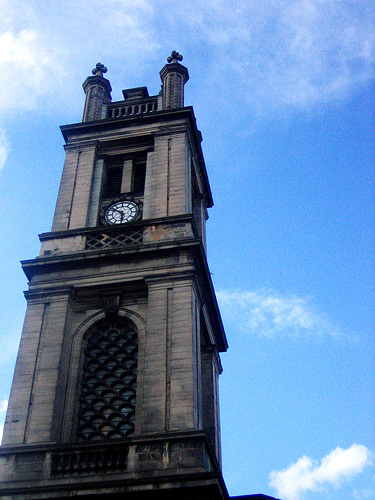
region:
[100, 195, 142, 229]
a white clock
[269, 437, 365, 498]
a white puff cloud in the sky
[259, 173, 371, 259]
a clear blue sky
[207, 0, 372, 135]
blue sky with white clouds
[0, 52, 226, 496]
a large tower with a clock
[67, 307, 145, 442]
a large window in a tower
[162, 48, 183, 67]
artwork at the top of a tower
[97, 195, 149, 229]
a clock on a tower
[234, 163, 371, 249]
vast blue sky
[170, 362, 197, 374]
gray stone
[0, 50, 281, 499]
a tall clock tower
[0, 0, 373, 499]
a large area of blue sky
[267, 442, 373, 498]
a white cloud in the sky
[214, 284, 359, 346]
a white cloud in the sky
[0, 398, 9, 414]
a white cloud in the sky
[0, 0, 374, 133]
a group of white clouds in the sky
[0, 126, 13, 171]
a white cloud in the sky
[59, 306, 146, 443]
a decorative arch on the tower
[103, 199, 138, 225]
a clock on the tower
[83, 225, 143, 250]
a decorative grating on the tower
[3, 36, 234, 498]
This is a tower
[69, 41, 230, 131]
two posts on the top of the tower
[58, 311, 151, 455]
pne arch window with scale detail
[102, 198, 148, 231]
clock in the clock tower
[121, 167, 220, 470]
tower made of brick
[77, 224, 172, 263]
cross hatch pattern made of metal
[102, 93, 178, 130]
brick fence on the top of the tower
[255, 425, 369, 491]
light clouds in the sky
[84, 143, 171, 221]
room above the clock in the tower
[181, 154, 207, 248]
window in the clock tower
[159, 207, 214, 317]
corner and ledge on the tower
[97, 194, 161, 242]
clock's hands are black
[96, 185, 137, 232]
clock's hands are black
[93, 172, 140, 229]
clock's face is white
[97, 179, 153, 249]
clock's face is white